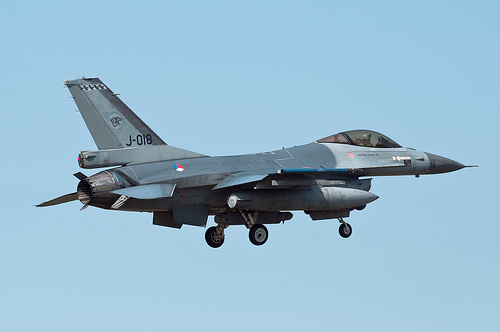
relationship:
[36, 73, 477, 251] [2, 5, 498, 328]
airplane in air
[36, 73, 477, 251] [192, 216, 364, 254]
airplane has wheels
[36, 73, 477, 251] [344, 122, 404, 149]
airplane has whindshield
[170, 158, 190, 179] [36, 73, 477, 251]
logo on airplane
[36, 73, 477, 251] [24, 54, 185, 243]
airplane has back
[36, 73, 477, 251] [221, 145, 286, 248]
airplane has middle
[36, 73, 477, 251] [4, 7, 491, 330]
airplane in sky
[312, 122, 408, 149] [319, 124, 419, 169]
window over cockpit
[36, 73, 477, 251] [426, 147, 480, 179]
airplane has nose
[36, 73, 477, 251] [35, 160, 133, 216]
airplane has engine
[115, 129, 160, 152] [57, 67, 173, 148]
writing on tail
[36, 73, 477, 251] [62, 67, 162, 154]
airplane has tail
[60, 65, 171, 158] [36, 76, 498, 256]
tail on jet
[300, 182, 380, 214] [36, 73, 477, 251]
missile on airplane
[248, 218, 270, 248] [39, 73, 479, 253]
wheel on airplane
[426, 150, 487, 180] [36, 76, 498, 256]
nose on jet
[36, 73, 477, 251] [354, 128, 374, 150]
airplane has pilot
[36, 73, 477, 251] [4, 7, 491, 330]
airplane flying in sky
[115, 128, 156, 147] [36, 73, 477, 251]
letters on airplane